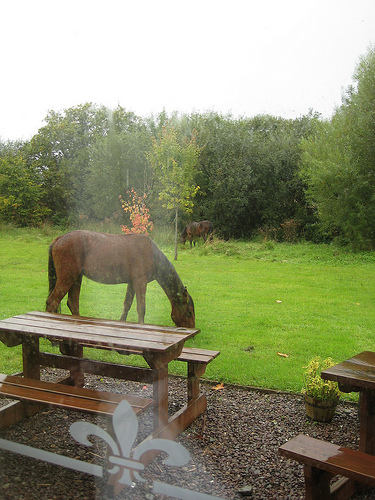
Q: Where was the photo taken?
A: It was taken at the backyard.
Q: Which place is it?
A: It is a backyard.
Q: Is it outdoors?
A: Yes, it is outdoors.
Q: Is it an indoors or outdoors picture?
A: It is outdoors.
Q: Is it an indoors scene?
A: No, it is outdoors.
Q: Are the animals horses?
A: Yes, all the animals are horses.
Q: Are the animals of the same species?
A: Yes, all the animals are horses.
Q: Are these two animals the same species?
A: Yes, all the animals are horses.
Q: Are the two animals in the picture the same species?
A: Yes, all the animals are horses.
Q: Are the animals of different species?
A: No, all the animals are horses.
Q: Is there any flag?
A: No, there are no flags.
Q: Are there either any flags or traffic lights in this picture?
A: No, there are no flags or traffic lights.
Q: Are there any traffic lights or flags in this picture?
A: No, there are no flags or traffic lights.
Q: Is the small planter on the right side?
A: Yes, the planter is on the right of the image.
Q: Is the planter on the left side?
A: No, the planter is on the right of the image.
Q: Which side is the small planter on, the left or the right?
A: The planter is on the right of the image.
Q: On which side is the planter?
A: The planter is on the right of the image.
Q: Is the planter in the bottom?
A: Yes, the planter is in the bottom of the image.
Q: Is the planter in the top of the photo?
A: No, the planter is in the bottom of the image.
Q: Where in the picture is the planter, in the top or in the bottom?
A: The planter is in the bottom of the image.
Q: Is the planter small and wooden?
A: Yes, the planter is small and wooden.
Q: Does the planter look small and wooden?
A: Yes, the planter is small and wooden.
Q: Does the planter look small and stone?
A: No, the planter is small but wooden.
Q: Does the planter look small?
A: Yes, the planter is small.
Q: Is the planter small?
A: Yes, the planter is small.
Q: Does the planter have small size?
A: Yes, the planter is small.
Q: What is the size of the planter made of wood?
A: The planter is small.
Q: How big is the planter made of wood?
A: The planter is small.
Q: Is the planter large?
A: No, the planter is small.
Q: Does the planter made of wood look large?
A: No, the planter is small.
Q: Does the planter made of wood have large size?
A: No, the planter is small.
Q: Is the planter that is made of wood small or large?
A: The planter is small.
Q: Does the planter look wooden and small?
A: Yes, the planter is wooden and small.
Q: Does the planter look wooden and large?
A: No, the planter is wooden but small.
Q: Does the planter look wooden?
A: Yes, the planter is wooden.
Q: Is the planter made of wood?
A: Yes, the planter is made of wood.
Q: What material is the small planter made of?
A: The planter is made of wood.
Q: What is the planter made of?
A: The planter is made of wood.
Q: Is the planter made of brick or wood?
A: The planter is made of wood.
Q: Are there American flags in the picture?
A: No, there are no American flags.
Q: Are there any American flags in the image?
A: No, there are no American flags.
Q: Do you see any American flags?
A: No, there are no American flags.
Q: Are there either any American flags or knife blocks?
A: No, there are no American flags or knife blocks.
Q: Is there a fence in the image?
A: No, there are no fences.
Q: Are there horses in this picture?
A: Yes, there is a horse.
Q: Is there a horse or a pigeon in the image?
A: Yes, there is a horse.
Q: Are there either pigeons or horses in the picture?
A: Yes, there is a horse.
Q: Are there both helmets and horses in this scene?
A: No, there is a horse but no helmets.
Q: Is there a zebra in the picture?
A: No, there are no zebras.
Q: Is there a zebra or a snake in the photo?
A: No, there are no zebras or snakes.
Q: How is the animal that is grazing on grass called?
A: The animal is a horse.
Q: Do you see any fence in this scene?
A: No, there are no fences.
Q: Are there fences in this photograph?
A: No, there are no fences.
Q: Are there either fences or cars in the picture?
A: No, there are no fences or cars.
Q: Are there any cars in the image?
A: No, there are no cars.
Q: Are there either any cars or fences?
A: No, there are no cars or fences.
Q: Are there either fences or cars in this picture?
A: No, there are no cars or fences.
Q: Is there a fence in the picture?
A: No, there are no fences.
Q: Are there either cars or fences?
A: No, there are no fences or cars.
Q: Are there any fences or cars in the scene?
A: No, there are no fences or cars.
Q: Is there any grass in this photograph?
A: Yes, there is grass.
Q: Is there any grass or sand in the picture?
A: Yes, there is grass.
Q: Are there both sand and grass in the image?
A: No, there is grass but no sand.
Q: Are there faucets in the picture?
A: No, there are no faucets.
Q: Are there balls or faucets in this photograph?
A: No, there are no faucets or balls.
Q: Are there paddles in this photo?
A: No, there are no paddles.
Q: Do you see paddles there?
A: No, there are no paddles.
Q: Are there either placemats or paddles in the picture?
A: No, there are no paddles or placemats.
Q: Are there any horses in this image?
A: Yes, there is a horse.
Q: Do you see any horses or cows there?
A: Yes, there is a horse.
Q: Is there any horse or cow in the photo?
A: Yes, there is a horse.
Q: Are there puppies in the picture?
A: No, there are no puppies.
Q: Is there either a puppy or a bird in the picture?
A: No, there are no puppies or birds.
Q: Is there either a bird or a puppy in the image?
A: No, there are no puppies or birds.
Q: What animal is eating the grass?
A: The horse is eating the grass.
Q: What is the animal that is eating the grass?
A: The animal is a horse.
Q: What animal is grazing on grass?
A: The horse is grazing on grass.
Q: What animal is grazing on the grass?
A: The horse is grazing on grass.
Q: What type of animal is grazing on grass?
A: The animal is a horse.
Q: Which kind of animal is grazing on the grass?
A: The animal is a horse.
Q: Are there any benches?
A: Yes, there is a bench.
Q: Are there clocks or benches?
A: Yes, there is a bench.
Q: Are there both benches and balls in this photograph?
A: No, there is a bench but no balls.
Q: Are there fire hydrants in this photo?
A: No, there are no fire hydrants.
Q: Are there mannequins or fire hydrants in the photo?
A: No, there are no fire hydrants or mannequins.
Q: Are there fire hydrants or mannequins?
A: No, there are no fire hydrants or mannequins.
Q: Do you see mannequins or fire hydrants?
A: No, there are no fire hydrants or mannequins.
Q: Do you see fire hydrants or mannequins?
A: No, there are no fire hydrants or mannequins.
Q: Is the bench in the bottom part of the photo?
A: Yes, the bench is in the bottom of the image.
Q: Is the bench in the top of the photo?
A: No, the bench is in the bottom of the image.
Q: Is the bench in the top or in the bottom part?
A: The bench is in the bottom of the image.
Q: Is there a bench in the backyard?
A: Yes, there is a bench in the backyard.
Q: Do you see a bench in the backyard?
A: Yes, there is a bench in the backyard.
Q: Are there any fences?
A: No, there are no fences.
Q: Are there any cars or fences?
A: No, there are no fences or cars.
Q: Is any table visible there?
A: Yes, there is a table.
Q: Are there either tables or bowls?
A: Yes, there is a table.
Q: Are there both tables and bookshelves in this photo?
A: No, there is a table but no bookshelves.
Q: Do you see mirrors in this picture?
A: No, there are no mirrors.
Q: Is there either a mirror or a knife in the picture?
A: No, there are no mirrors or knives.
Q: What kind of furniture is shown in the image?
A: The furniture is a table.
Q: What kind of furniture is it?
A: The piece of furniture is a table.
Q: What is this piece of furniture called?
A: This is a table.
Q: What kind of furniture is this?
A: This is a table.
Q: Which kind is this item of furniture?
A: This is a table.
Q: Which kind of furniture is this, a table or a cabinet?
A: This is a table.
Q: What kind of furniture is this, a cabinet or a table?
A: This is a table.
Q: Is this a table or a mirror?
A: This is a table.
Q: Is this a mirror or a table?
A: This is a table.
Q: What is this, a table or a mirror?
A: This is a table.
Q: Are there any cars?
A: No, there are no cars.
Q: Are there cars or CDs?
A: No, there are no cars or cds.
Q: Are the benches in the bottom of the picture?
A: Yes, the benches are in the bottom of the image.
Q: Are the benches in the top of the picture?
A: No, the benches are in the bottom of the image.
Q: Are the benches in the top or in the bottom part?
A: The benches are in the bottom of the image.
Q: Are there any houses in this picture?
A: No, there are no houses.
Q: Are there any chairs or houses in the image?
A: No, there are no houses or chairs.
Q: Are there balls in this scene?
A: No, there are no balls.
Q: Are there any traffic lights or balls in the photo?
A: No, there are no balls or traffic lights.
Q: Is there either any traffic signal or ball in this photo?
A: No, there are no balls or traffic lights.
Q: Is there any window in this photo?
A: Yes, there is a window.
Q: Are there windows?
A: Yes, there is a window.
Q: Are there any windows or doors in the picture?
A: Yes, there is a window.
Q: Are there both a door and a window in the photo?
A: No, there is a window but no doors.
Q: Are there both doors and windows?
A: No, there is a window but no doors.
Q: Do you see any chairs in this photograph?
A: No, there are no chairs.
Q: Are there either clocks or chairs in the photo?
A: No, there are no chairs or clocks.